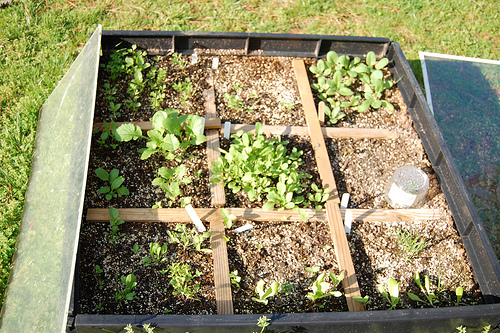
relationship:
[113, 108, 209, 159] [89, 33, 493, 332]
plant in container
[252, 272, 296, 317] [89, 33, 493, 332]
plant in container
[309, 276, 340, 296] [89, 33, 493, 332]
plant in container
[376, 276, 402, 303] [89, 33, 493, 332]
plant in container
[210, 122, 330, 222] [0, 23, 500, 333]
plant in bed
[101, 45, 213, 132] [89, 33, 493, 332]
plant in container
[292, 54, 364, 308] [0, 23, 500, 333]
wood divider in bed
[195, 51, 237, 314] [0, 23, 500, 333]
wood divider in bed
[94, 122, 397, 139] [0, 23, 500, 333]
wood bar in bed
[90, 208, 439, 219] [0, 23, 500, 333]
wood bar in bed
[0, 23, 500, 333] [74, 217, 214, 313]
bed for section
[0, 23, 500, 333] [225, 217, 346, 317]
bed for section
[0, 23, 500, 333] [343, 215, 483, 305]
bed for section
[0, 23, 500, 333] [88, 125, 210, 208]
bed for section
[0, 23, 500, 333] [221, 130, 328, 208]
bed for section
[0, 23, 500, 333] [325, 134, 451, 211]
bed for section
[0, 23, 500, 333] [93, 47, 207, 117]
bed for section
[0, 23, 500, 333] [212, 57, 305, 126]
bed for section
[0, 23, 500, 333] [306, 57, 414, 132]
bed for section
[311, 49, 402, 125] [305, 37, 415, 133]
plant grown in corner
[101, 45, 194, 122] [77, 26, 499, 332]
plant in box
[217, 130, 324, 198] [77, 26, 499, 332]
plant in box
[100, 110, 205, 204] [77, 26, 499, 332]
plant in box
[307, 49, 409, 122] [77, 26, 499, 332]
plant in box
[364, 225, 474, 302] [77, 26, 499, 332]
plant in box